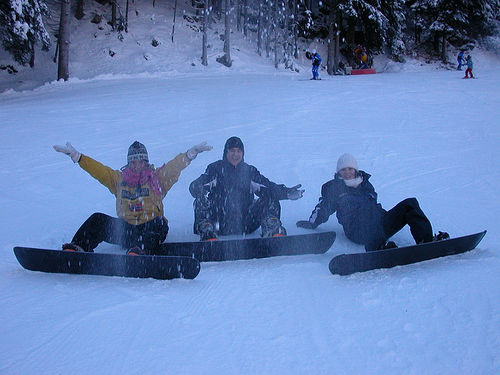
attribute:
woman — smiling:
[307, 157, 438, 242]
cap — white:
[333, 151, 361, 174]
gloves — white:
[54, 131, 217, 169]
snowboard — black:
[156, 233, 332, 257]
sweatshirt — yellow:
[75, 152, 191, 221]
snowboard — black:
[330, 224, 486, 278]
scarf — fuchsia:
[124, 165, 160, 194]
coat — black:
[194, 160, 286, 205]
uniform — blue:
[310, 54, 319, 67]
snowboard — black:
[15, 242, 199, 282]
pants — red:
[463, 67, 476, 77]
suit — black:
[317, 182, 433, 241]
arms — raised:
[54, 137, 209, 197]